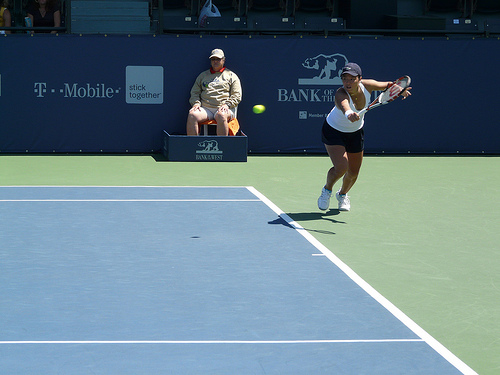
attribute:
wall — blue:
[1, 34, 499, 154]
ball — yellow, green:
[252, 104, 265, 114]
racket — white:
[357, 74, 410, 119]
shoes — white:
[319, 188, 332, 211]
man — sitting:
[187, 48, 242, 135]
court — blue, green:
[2, 188, 466, 374]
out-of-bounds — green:
[0, 154, 498, 185]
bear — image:
[302, 53, 349, 78]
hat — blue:
[341, 62, 362, 77]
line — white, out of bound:
[1, 184, 253, 190]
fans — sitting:
[1, 2, 61, 35]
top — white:
[326, 82, 372, 132]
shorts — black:
[322, 116, 364, 153]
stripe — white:
[1, 184, 254, 190]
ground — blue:
[2, 154, 500, 372]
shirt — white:
[324, 82, 371, 133]